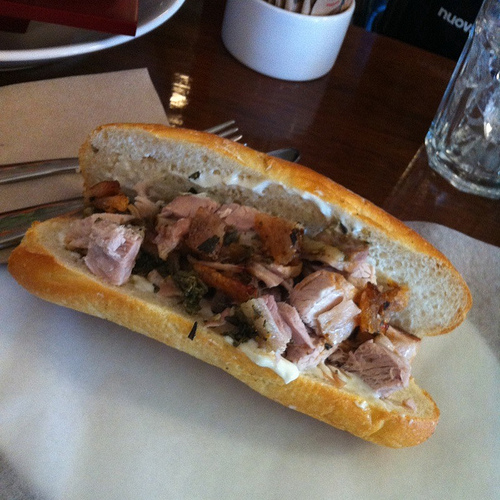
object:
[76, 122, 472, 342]
bread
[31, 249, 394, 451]
edge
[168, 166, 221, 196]
cream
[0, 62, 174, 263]
cloth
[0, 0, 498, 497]
table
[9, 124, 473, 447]
sandwich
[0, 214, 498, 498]
napkin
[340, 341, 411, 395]
meat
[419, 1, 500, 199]
glass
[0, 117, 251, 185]
fork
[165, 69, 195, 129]
light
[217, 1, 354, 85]
condiment dish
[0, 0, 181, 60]
plate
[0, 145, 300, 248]
spoon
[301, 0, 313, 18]
sugar packet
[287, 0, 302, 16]
sugar packet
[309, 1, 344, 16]
sugar packet